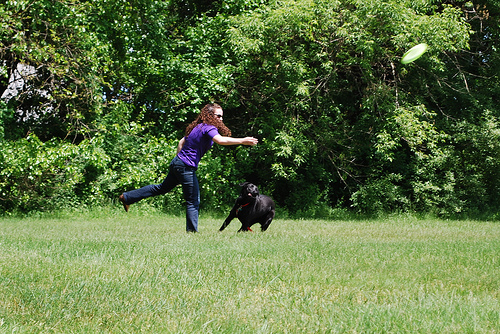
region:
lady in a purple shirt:
[107, 98, 256, 229]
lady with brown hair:
[103, 102, 259, 236]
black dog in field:
[200, 181, 293, 243]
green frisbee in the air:
[394, 33, 434, 75]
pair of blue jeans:
[113, 152, 210, 231]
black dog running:
[212, 169, 289, 237]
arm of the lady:
[202, 126, 267, 150]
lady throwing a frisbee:
[100, 98, 257, 240]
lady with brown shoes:
[100, 96, 272, 243]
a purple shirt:
[167, 119, 222, 170]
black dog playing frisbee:
[216, 177, 276, 237]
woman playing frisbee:
[114, 102, 254, 237]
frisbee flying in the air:
[399, 41, 428, 69]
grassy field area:
[0, 217, 494, 333]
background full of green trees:
[0, 0, 497, 220]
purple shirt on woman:
[176, 122, 221, 169]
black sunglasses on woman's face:
[214, 112, 226, 119]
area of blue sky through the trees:
[2, 48, 51, 129]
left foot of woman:
[116, 190, 133, 212]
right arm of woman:
[205, 125, 265, 146]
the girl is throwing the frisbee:
[87, 31, 444, 267]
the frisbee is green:
[387, 30, 429, 82]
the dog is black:
[219, 170, 283, 244]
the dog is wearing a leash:
[238, 195, 248, 222]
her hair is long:
[202, 109, 234, 134]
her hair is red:
[199, 105, 212, 125]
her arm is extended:
[204, 120, 263, 166]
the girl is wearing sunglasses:
[205, 107, 223, 119]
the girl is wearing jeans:
[122, 152, 202, 224]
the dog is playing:
[222, 170, 275, 237]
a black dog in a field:
[220, 182, 278, 235]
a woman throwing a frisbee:
[118, 92, 255, 231]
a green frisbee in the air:
[398, 36, 434, 66]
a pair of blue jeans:
[118, 158, 200, 232]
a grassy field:
[13, 211, 489, 326]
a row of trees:
[3, 6, 482, 218]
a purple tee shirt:
[177, 118, 218, 165]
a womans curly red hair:
[189, 99, 236, 131]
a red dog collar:
[234, 196, 254, 208]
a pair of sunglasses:
[210, 110, 227, 118]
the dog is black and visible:
[137, 88, 387, 282]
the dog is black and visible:
[225, 148, 347, 329]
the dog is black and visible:
[197, 180, 319, 297]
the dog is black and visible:
[230, 202, 310, 326]